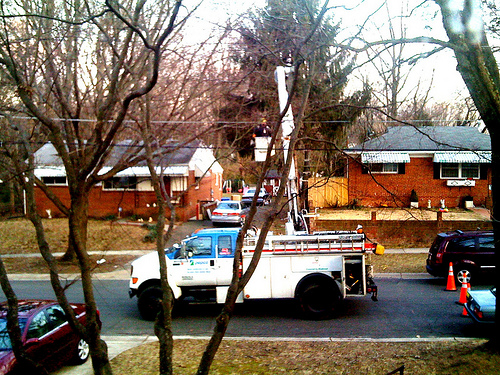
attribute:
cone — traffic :
[445, 257, 460, 292]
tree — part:
[213, 0, 372, 222]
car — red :
[0, 297, 101, 373]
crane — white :
[265, 59, 342, 241]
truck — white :
[123, 223, 380, 330]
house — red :
[344, 124, 494, 208]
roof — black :
[346, 124, 489, 154]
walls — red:
[35, 168, 229, 226]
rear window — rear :
[217, 200, 239, 211]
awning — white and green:
[357, 148, 414, 163]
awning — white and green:
[434, 155, 489, 162]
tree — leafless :
[41, 33, 166, 239]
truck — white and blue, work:
[128, 64, 385, 320]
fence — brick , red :
[325, 186, 481, 258]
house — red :
[339, 118, 490, 209]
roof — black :
[342, 120, 492, 156]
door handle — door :
[208, 260, 214, 270]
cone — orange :
[440, 259, 459, 293]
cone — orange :
[453, 272, 473, 302]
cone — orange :
[460, 295, 484, 320]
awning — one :
[429, 149, 484, 168]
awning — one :
[360, 146, 414, 162]